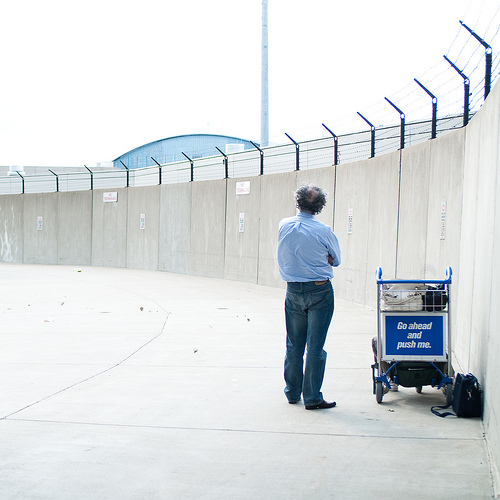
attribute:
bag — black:
[431, 370, 483, 420]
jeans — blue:
[279, 275, 339, 408]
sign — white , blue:
[374, 309, 452, 361]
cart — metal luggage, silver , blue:
[371, 265, 456, 404]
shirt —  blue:
[276, 210, 340, 282]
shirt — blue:
[273, 214, 341, 284]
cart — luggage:
[369, 266, 449, 408]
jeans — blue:
[272, 275, 339, 408]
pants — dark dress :
[241, 293, 398, 418]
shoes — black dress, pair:
[263, 333, 385, 425]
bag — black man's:
[428, 371, 484, 418]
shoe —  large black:
[303, 399, 333, 412]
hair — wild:
[287, 181, 337, 216]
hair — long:
[299, 190, 319, 203]